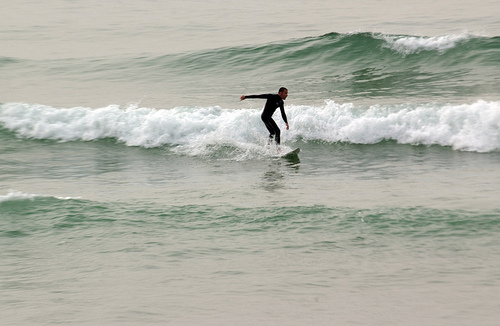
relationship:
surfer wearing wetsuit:
[239, 86, 290, 157] [242, 93, 287, 153]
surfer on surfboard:
[239, 86, 290, 157] [244, 144, 301, 162]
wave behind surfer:
[1, 100, 499, 162] [239, 86, 290, 157]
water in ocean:
[0, 0, 497, 92] [0, 1, 499, 325]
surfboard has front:
[244, 144, 301, 162] [282, 146, 303, 158]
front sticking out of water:
[282, 146, 303, 158] [0, 0, 500, 326]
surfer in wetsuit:
[239, 86, 290, 157] [242, 93, 287, 153]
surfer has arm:
[239, 86, 290, 157] [239, 93, 271, 100]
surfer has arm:
[239, 86, 290, 157] [278, 103, 291, 131]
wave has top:
[166, 31, 499, 87] [364, 28, 485, 59]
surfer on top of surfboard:
[239, 86, 290, 157] [244, 144, 301, 162]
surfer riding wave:
[239, 86, 290, 157] [1, 100, 499, 162]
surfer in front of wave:
[239, 86, 290, 157] [166, 31, 499, 87]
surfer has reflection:
[239, 86, 290, 157] [261, 145, 286, 192]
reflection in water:
[261, 145, 286, 192] [0, 0, 500, 326]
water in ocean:
[0, 0, 500, 326] [0, 1, 499, 325]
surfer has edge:
[239, 86, 290, 157] [266, 147, 299, 164]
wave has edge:
[1, 100, 499, 162] [1, 126, 500, 160]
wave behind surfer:
[166, 31, 499, 87] [239, 86, 290, 157]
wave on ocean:
[1, 100, 499, 162] [0, 1, 499, 325]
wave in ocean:
[1, 100, 499, 162] [0, 1, 499, 325]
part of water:
[190, 171, 485, 281] [0, 0, 497, 92]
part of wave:
[37, 94, 257, 167] [1, 100, 499, 162]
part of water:
[127, 35, 273, 95] [0, 0, 497, 92]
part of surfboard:
[254, 137, 330, 173] [244, 144, 301, 162]